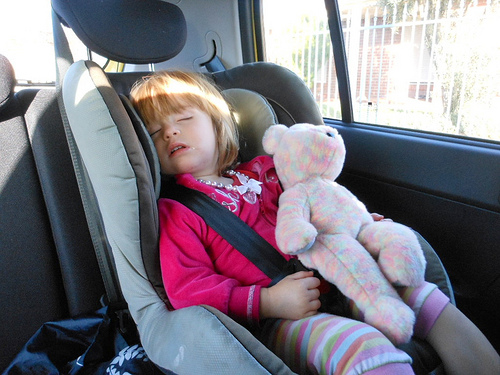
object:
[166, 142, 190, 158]
mouth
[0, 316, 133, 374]
blue article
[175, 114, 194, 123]
eye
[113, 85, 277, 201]
headrest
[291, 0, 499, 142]
fence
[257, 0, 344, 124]
window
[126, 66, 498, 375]
child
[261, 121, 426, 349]
bear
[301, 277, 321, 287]
finger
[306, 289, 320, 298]
finger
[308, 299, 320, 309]
finger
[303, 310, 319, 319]
finger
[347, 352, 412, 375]
stripe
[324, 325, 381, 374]
stripe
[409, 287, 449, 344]
stripe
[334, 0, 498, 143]
window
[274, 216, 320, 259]
paw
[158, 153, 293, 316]
pink jacket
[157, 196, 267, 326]
arm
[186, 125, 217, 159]
cheek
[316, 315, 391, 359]
lap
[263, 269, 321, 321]
hand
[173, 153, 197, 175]
chin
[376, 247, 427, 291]
paw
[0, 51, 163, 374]
seat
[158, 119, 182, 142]
nose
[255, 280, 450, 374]
pants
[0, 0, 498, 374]
car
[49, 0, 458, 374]
seat